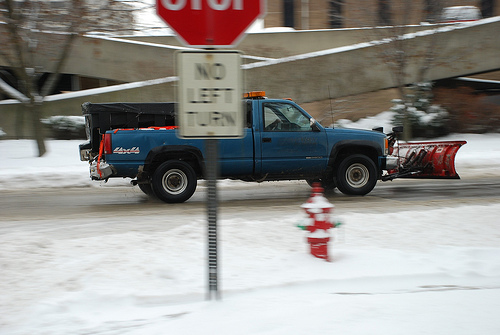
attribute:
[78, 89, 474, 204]
truck — blue, passing by, pickup, 4x4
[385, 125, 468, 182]
plow — red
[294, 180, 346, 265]
hydrant — red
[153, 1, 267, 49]
sign — red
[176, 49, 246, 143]
traffic sign — black, white, black traffic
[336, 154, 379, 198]
tire — blackwall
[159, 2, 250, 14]
stop — red, white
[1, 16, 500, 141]
ramps — grey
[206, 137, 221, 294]
post — metal sign 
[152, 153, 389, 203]
tires — black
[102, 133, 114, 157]
tail light — red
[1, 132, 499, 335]
snow — white